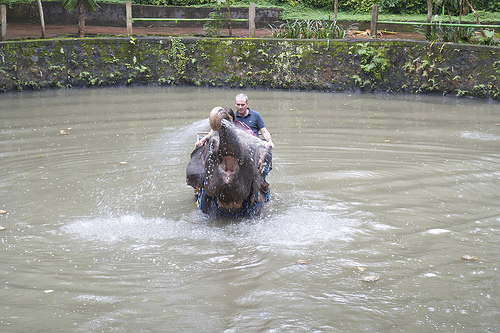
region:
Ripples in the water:
[21, 286, 56, 316]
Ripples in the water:
[60, 284, 109, 327]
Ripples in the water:
[107, 287, 140, 328]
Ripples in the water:
[153, 287, 200, 330]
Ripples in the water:
[218, 285, 284, 331]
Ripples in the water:
[282, 284, 330, 331]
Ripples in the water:
[333, 275, 372, 330]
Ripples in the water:
[367, 281, 426, 326]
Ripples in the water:
[439, 281, 470, 331]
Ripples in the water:
[343, 200, 388, 240]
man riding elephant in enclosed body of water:
[175, 85, 290, 218]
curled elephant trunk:
[200, 96, 251, 156]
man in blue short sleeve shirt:
[215, 85, 265, 135]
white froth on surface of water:
[415, 216, 455, 236]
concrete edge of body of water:
[2, 31, 497, 107]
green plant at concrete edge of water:
[263, 16, 345, 42]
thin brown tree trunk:
[32, 1, 53, 37]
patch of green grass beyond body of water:
[282, 3, 498, 33]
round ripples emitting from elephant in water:
[7, 112, 497, 179]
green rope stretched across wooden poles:
[127, 11, 250, 30]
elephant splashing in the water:
[180, 121, 276, 219]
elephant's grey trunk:
[209, 105, 244, 160]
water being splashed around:
[56, 190, 363, 263]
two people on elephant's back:
[216, 87, 278, 157]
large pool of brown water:
[3, 71, 499, 326]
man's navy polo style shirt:
[230, 106, 267, 141]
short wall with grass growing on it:
[3, 33, 498, 120]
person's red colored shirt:
[231, 120, 256, 136]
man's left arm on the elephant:
[254, 112, 279, 152]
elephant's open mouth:
[215, 150, 246, 184]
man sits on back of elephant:
[183, 90, 277, 224]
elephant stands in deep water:
[185, 93, 278, 225]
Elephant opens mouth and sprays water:
[184, 90, 275, 218]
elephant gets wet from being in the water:
[182, 92, 277, 222]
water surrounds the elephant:
[1, 84, 498, 331]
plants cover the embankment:
[1, 0, 499, 101]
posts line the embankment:
[1, 0, 498, 45]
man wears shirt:
[192, 93, 277, 150]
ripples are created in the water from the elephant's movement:
[0, 86, 497, 328]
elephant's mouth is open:
[186, 105, 266, 207]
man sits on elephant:
[186, 83, 296, 220]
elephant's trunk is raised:
[205, 105, 260, 217]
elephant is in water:
[161, 111, 314, 266]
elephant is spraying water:
[134, 93, 289, 203]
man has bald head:
[229, 79, 254, 104]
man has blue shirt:
[219, 104, 257, 143]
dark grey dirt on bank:
[224, 26, 474, 124]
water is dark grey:
[369, 124, 475, 229]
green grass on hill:
[304, 1, 491, 24]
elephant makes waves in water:
[126, 77, 323, 254]